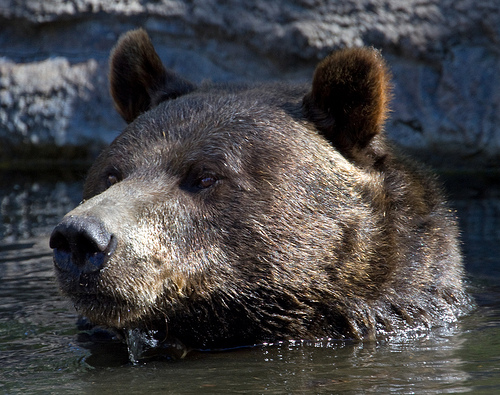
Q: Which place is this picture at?
A: It is at the river.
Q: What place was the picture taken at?
A: It was taken at the river.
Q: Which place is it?
A: It is a river.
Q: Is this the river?
A: Yes, it is the river.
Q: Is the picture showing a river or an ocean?
A: It is showing a river.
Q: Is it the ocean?
A: No, it is the river.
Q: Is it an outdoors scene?
A: Yes, it is outdoors.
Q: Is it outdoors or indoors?
A: It is outdoors.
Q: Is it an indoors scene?
A: No, it is outdoors.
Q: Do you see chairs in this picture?
A: No, there are no chairs.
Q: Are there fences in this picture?
A: No, there are no fences.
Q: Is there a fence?
A: No, there are no fences.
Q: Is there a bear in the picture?
A: Yes, there is a bear.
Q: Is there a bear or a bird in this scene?
A: Yes, there is a bear.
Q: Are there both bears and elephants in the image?
A: No, there is a bear but no elephants.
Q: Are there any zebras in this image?
A: No, there are no zebras.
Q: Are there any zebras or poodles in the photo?
A: No, there are no zebras or poodles.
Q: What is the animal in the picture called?
A: The animal is a bear.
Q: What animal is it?
A: The animal is a bear.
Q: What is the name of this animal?
A: This is a bear.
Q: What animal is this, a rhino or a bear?
A: This is a bear.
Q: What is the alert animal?
A: The animal is a bear.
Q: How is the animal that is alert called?
A: The animal is a bear.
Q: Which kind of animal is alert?
A: The animal is a bear.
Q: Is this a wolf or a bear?
A: This is a bear.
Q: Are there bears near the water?
A: Yes, there is a bear near the water.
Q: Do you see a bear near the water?
A: Yes, there is a bear near the water.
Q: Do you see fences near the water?
A: No, there is a bear near the water.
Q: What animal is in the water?
A: The bear is in the water.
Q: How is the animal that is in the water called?
A: The animal is a bear.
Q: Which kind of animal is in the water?
A: The animal is a bear.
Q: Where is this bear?
A: The bear is in the water.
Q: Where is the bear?
A: The bear is in the water.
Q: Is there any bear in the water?
A: Yes, there is a bear in the water.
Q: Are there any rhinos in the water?
A: No, there is a bear in the water.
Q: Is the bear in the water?
A: Yes, the bear is in the water.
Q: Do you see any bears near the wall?
A: Yes, there is a bear near the wall.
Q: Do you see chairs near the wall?
A: No, there is a bear near the wall.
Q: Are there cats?
A: No, there are no cats.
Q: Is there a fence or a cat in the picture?
A: No, there are no cats or fences.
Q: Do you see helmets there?
A: No, there are no helmets.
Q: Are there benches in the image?
A: No, there are no benches.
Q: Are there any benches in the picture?
A: No, there are no benches.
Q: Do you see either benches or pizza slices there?
A: No, there are no benches or pizza slices.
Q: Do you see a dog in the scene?
A: No, there are no dogs.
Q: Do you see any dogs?
A: No, there are no dogs.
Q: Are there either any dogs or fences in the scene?
A: No, there are no dogs or fences.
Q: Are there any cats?
A: No, there are no cats.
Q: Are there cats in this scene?
A: No, there are no cats.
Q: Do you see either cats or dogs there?
A: No, there are no cats or dogs.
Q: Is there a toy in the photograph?
A: No, there are no toys.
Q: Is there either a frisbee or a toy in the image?
A: No, there are no toys or frisbees.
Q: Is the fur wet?
A: Yes, the fur is wet.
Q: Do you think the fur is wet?
A: Yes, the fur is wet.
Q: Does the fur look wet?
A: Yes, the fur is wet.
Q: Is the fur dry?
A: No, the fur is wet.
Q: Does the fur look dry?
A: No, the fur is wet.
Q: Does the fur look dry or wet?
A: The fur is wet.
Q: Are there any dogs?
A: No, there are no dogs.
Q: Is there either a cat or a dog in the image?
A: No, there are no dogs or cats.